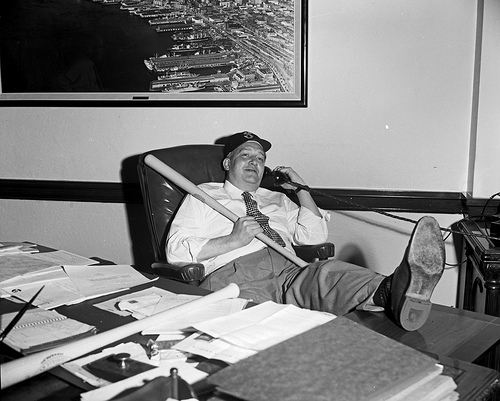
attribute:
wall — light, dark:
[413, 46, 416, 47]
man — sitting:
[224, 136, 352, 293]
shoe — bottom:
[397, 229, 430, 332]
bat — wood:
[149, 146, 223, 196]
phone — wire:
[270, 172, 289, 184]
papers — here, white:
[48, 262, 103, 288]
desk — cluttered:
[80, 307, 111, 316]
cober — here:
[72, 247, 89, 266]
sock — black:
[377, 291, 387, 303]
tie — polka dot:
[243, 194, 250, 211]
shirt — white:
[184, 225, 200, 231]